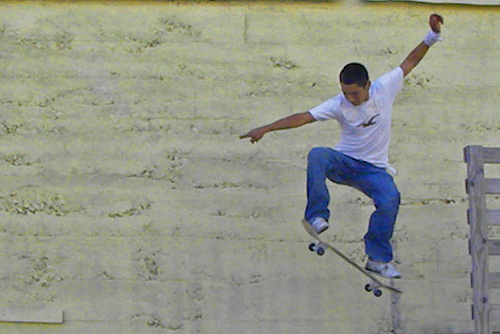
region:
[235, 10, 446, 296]
young man on skateboard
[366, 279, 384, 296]
wheels on the skateboard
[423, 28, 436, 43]
white band on wrist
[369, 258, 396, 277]
athletic shoe on foot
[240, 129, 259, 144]
fingers on man's hand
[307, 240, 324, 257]
the wheels are black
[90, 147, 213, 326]
cracks in the wall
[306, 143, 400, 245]
the jeans are blue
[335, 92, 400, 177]
the shirt is white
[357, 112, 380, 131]
the emblem is black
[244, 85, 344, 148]
the arms are stretched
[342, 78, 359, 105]
the face is dark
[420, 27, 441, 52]
band on the wrist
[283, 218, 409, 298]
this is a skateboard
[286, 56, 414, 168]
man wearing a white shirt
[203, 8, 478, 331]
man is in the air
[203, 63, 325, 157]
man has arm extended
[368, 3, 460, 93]
man has arm raised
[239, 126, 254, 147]
man is pointing finge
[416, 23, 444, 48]
a white wrist band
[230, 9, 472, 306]
this is a man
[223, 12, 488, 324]
man on a skateboard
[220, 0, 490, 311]
man is doing a trick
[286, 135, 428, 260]
man is wearing blue jeans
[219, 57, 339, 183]
man has arm extended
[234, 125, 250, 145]
man is pointing finger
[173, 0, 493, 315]
man and board in the air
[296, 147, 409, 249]
man wearing blue jeans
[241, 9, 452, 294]
man jumping on skateboard with arms extended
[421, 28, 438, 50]
man wearing white asweat band on arm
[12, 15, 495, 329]
white stone wall behind skateboarder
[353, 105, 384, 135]
black bird on white shirt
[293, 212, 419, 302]
skateboard in mid air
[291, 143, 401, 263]
man wearing blue jeans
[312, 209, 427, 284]
man wearing white tennis shoes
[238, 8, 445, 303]
man standing on skateboard in air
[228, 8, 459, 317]
a person riding a skateboard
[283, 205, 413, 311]
a skateboard in the air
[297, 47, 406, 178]
a white hollister shirt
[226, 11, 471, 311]
man jumping in the air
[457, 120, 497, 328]
a wooden pallet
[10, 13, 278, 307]
a gray brick wall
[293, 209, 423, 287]
a pair skate shoes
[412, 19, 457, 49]
a white sweatband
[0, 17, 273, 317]
white wall behind skater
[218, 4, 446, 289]
skater doing a trick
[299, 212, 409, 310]
skateboard beneath skater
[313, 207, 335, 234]
shoe on skater's foot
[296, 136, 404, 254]
jeans on skaters legs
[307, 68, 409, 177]
shirt on skater's body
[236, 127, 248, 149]
skater's extended index finger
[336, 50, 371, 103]
head on skater's shoulders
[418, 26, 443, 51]
sweatband on skater's left arm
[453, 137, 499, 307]
palette right of skater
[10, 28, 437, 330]
this is a skate park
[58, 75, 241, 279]
this is a stone wall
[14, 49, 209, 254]
the wall is cracking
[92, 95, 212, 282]
the wall is old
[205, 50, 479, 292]
the boy is jumping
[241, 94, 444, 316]
the boy is skating